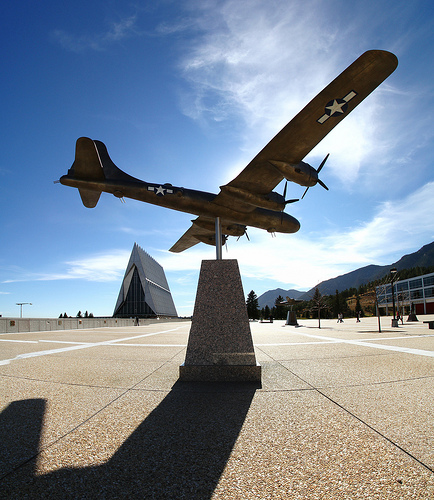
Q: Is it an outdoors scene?
A: Yes, it is outdoors.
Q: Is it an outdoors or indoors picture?
A: It is outdoors.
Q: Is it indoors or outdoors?
A: It is outdoors.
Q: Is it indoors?
A: No, it is outdoors.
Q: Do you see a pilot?
A: No, there are no pilots.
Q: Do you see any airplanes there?
A: Yes, there is an airplane.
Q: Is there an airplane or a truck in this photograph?
A: Yes, there is an airplane.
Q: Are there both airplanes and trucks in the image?
A: No, there is an airplane but no trucks.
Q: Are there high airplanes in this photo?
A: Yes, there is a high airplane.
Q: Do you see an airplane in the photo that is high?
A: Yes, there is an airplane that is high.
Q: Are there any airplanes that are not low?
A: Yes, there is a high airplane.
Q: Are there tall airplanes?
A: Yes, there is a tall airplane.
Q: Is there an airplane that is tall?
A: Yes, there is an airplane that is tall.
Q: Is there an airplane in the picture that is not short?
A: Yes, there is a tall airplane.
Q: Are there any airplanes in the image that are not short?
A: Yes, there is a tall airplane.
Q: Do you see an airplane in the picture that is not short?
A: Yes, there is a tall airplane.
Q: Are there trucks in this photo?
A: No, there are no trucks.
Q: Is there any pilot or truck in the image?
A: No, there are no trucks or pilots.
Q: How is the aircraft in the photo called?
A: The aircraft is an airplane.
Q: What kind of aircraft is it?
A: The aircraft is an airplane.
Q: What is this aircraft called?
A: That is an airplane.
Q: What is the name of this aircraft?
A: That is an airplane.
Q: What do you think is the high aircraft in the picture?
A: The aircraft is an airplane.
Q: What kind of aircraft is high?
A: The aircraft is an airplane.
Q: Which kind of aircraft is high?
A: The aircraft is an airplane.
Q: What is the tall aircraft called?
A: The aircraft is an airplane.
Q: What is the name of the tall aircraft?
A: The aircraft is an airplane.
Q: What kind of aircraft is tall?
A: The aircraft is an airplane.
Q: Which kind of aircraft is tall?
A: The aircraft is an airplane.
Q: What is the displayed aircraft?
A: The aircraft is an airplane.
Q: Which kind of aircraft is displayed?
A: The aircraft is an airplane.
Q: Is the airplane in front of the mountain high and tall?
A: Yes, the airplane is high and tall.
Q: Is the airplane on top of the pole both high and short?
A: No, the airplane is high but tall.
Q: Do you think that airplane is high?
A: Yes, the airplane is high.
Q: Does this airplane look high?
A: Yes, the airplane is high.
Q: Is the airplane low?
A: No, the airplane is high.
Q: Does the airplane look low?
A: No, the airplane is high.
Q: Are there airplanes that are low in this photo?
A: No, there is an airplane but it is high.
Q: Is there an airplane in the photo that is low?
A: No, there is an airplane but it is high.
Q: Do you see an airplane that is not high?
A: No, there is an airplane but it is high.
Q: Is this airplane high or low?
A: The airplane is high.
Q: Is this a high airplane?
A: Yes, this is a high airplane.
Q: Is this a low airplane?
A: No, this is a high airplane.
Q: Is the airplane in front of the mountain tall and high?
A: Yes, the plane is tall and high.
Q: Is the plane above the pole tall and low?
A: No, the airplane is tall but high.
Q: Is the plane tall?
A: Yes, the plane is tall.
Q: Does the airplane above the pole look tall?
A: Yes, the airplane is tall.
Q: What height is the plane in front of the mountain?
A: The plane is tall.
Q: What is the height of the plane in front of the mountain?
A: The plane is tall.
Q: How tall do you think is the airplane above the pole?
A: The airplane is tall.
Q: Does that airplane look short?
A: No, the airplane is tall.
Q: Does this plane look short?
A: No, the plane is tall.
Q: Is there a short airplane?
A: No, there is an airplane but it is tall.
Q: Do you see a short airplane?
A: No, there is an airplane but it is tall.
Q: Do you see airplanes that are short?
A: No, there is an airplane but it is tall.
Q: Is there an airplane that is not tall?
A: No, there is an airplane but it is tall.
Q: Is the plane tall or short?
A: The plane is tall.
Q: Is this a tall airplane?
A: Yes, this is a tall airplane.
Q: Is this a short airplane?
A: No, this is a tall airplane.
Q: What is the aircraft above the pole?
A: The aircraft is an airplane.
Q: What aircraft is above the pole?
A: The aircraft is an airplane.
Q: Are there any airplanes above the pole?
A: Yes, there is an airplane above the pole.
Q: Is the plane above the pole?
A: Yes, the plane is above the pole.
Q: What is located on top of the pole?
A: The plane is on top of the pole.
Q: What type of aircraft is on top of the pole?
A: The aircraft is an airplane.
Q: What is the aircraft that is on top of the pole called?
A: The aircraft is an airplane.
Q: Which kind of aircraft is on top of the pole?
A: The aircraft is an airplane.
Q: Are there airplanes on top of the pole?
A: Yes, there is an airplane on top of the pole.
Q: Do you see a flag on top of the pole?
A: No, there is an airplane on top of the pole.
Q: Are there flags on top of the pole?
A: No, there is an airplane on top of the pole.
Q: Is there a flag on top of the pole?
A: No, there is an airplane on top of the pole.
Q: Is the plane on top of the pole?
A: Yes, the plane is on top of the pole.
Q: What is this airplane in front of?
A: The airplane is in front of the mountain.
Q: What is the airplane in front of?
A: The airplane is in front of the mountain.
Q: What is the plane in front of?
A: The plane is in front of the mountain.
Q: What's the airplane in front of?
A: The plane is in front of the mountain.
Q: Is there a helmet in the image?
A: No, there are no helmets.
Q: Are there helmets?
A: No, there are no helmets.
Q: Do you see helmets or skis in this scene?
A: No, there are no helmets or skis.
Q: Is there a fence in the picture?
A: No, there are no fences.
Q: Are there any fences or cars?
A: No, there are no fences or cars.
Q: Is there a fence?
A: No, there are no fences.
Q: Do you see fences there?
A: No, there are no fences.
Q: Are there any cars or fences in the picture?
A: No, there are no fences or cars.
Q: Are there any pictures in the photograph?
A: No, there are no pictures.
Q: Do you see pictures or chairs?
A: No, there are no pictures or chairs.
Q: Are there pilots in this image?
A: No, there are no pilots.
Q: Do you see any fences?
A: No, there are no fences.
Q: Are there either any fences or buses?
A: No, there are no fences or buses.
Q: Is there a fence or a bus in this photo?
A: No, there are no fences or buses.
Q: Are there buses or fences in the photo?
A: No, there are no fences or buses.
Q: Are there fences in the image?
A: No, there are no fences.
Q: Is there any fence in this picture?
A: No, there are no fences.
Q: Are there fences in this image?
A: No, there are no fences.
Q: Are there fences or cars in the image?
A: No, there are no fences or cars.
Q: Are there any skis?
A: No, there are no skis.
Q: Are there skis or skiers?
A: No, there are no skis or skiers.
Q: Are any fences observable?
A: No, there are no fences.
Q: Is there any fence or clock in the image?
A: No, there are no fences or clocks.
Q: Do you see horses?
A: No, there are no horses.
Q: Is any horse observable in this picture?
A: No, there are no horses.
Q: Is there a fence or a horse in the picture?
A: No, there are no horses or fences.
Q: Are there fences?
A: No, there are no fences.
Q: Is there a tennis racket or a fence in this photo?
A: No, there are no fences or rackets.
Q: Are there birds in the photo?
A: No, there are no birds.